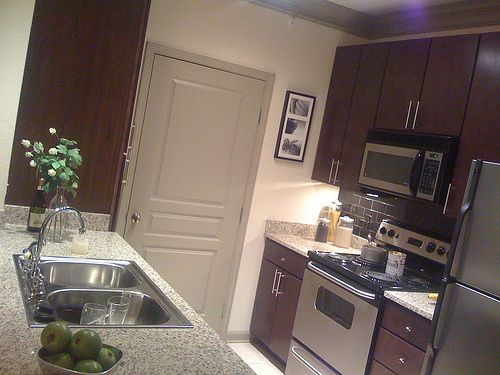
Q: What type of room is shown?
A: A kitchen.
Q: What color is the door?
A: White.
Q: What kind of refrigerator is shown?
A: Stainless steel.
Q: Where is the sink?
A: On the left.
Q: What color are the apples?
A: Green.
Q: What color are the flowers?
A: White.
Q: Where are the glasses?
A: In the sink.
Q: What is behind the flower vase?
A: Wine bottle.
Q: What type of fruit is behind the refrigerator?
A: Banana.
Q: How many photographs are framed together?
A: Three.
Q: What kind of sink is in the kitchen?
A: Stainless steel.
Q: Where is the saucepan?
A: On the stove.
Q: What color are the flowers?
A: White.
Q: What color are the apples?
A: Green.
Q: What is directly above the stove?
A: Microwave.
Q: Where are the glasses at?
A: In the sink.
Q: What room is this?
A: Kitchen.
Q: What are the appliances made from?
A: Stainless steel.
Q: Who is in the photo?
A: No one.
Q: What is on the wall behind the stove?
A: Tile.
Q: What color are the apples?
A: Green.